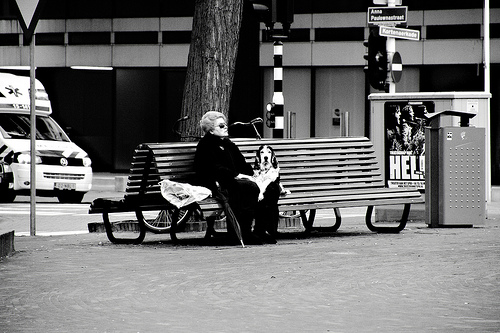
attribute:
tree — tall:
[186, 10, 247, 145]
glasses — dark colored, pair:
[213, 124, 249, 131]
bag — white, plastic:
[146, 180, 221, 217]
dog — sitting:
[254, 139, 291, 200]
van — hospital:
[1, 74, 108, 202]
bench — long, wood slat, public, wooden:
[115, 135, 375, 219]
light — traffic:
[360, 28, 390, 87]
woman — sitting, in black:
[198, 104, 258, 242]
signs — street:
[368, 7, 418, 78]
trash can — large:
[426, 111, 489, 236]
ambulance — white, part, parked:
[0, 61, 90, 199]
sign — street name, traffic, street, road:
[359, 8, 418, 20]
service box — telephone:
[373, 93, 487, 192]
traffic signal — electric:
[367, 28, 388, 93]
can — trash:
[419, 115, 485, 237]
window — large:
[255, 64, 423, 131]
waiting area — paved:
[12, 119, 500, 310]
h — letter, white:
[384, 155, 402, 181]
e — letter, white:
[404, 157, 412, 179]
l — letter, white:
[410, 157, 420, 183]